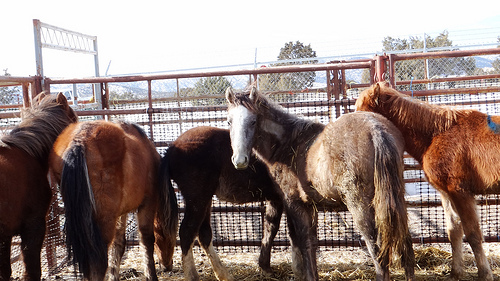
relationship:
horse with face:
[216, 83, 418, 275] [227, 107, 257, 168]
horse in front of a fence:
[216, 83, 418, 275] [110, 57, 224, 124]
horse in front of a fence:
[353, 76, 498, 279] [110, 57, 224, 124]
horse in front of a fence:
[158, 124, 303, 279] [110, 57, 224, 124]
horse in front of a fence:
[48, 117, 178, 279] [110, 57, 224, 124]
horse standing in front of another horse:
[216, 83, 418, 275] [161, 124, 284, 274]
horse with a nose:
[216, 83, 418, 275] [228, 151, 246, 163]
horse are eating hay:
[354, 82, 500, 281] [413, 240, 455, 278]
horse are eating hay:
[354, 82, 500, 281] [316, 247, 376, 277]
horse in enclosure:
[354, 82, 500, 281] [1, 22, 497, 249]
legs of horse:
[4, 219, 44, 280] [0, 85, 80, 275]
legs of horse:
[288, 199, 390, 271] [226, 84, 404, 273]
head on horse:
[214, 81, 265, 179] [216, 83, 418, 275]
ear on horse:
[248, 75, 262, 111] [216, 83, 418, 275]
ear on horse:
[224, 85, 236, 103] [216, 83, 418, 275]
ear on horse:
[249, 81, 258, 101] [216, 83, 418, 275]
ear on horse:
[369, 82, 381, 101] [353, 76, 498, 279]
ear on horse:
[383, 81, 392, 86] [353, 76, 498, 279]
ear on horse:
[53, 91, 70, 111] [0, 85, 80, 275]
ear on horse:
[57, 92, 69, 111] [0, 85, 80, 275]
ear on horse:
[225, 86, 236, 104] [215, 80, 441, 280]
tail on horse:
[369, 133, 412, 249] [216, 83, 418, 275]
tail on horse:
[62, 143, 100, 281] [43, 106, 193, 279]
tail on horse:
[157, 154, 172, 236] [149, 96, 298, 279]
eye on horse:
[244, 119, 259, 134] [221, 75, 434, 272]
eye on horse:
[251, 120, 257, 125] [216, 83, 418, 275]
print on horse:
[475, 105, 497, 143] [353, 76, 498, 279]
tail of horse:
[153, 156, 177, 262] [187, 112, 413, 278]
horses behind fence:
[0, 45, 499, 278] [0, 53, 483, 257]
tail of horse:
[55, 137, 112, 279] [56, 122, 181, 272]